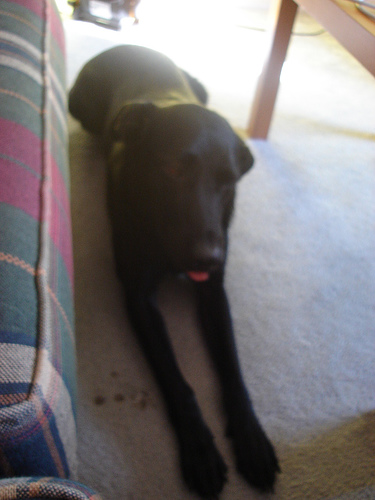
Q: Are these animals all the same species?
A: Yes, all the animals are dogs.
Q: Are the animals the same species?
A: Yes, all the animals are dogs.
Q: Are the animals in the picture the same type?
A: Yes, all the animals are dogs.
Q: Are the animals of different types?
A: No, all the animals are dogs.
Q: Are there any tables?
A: Yes, there is a table.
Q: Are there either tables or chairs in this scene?
A: Yes, there is a table.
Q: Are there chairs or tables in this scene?
A: Yes, there is a table.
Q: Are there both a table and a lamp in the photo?
A: No, there is a table but no lamps.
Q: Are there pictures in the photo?
A: No, there are no pictures.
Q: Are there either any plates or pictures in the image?
A: No, there are no pictures or plates.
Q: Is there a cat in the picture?
A: No, there are no cats.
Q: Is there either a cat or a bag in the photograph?
A: No, there are no cats or bags.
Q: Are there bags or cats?
A: No, there are no cats or bags.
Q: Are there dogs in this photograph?
A: Yes, there are dogs.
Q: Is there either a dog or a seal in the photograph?
A: Yes, there are dogs.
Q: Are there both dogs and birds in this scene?
A: No, there are dogs but no birds.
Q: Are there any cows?
A: No, there are no cows.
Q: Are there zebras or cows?
A: No, there are no cows or zebras.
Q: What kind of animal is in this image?
A: The animal is dogs.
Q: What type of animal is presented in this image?
A: The animal is dogs.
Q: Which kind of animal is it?
A: The animals are dogs.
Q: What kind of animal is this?
A: These are dogs.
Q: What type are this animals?
A: These are dogs.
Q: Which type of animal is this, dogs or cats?
A: These are dogs.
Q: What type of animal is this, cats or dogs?
A: These are dogs.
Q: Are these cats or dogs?
A: These are dogs.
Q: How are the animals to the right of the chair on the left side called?
A: The animals are dogs.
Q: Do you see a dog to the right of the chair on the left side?
A: Yes, there are dogs to the right of the chair.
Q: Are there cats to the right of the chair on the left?
A: No, there are dogs to the right of the chair.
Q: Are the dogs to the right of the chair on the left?
A: Yes, the dogs are to the right of the chair.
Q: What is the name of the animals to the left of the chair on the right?
A: The animals are dogs.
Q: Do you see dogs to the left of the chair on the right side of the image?
A: Yes, there are dogs to the left of the chair.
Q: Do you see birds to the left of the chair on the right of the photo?
A: No, there are dogs to the left of the chair.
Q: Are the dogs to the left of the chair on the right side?
A: Yes, the dogs are to the left of the chair.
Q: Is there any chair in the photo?
A: Yes, there is a chair.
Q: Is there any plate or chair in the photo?
A: Yes, there is a chair.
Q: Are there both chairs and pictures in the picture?
A: No, there is a chair but no pictures.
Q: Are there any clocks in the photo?
A: No, there are no clocks.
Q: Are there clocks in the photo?
A: No, there are no clocks.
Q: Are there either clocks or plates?
A: No, there are no clocks or plates.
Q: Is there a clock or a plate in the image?
A: No, there are no clocks or plates.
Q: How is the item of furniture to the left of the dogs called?
A: The piece of furniture is a chair.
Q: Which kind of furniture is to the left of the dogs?
A: The piece of furniture is a chair.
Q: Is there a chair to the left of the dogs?
A: Yes, there is a chair to the left of the dogs.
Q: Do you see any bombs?
A: No, there are no bombs.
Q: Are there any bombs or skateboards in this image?
A: No, there are no bombs or skateboards.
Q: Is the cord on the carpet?
A: Yes, the cord is on the carpet.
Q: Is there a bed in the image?
A: No, there are no beds.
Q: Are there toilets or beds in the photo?
A: No, there are no beds or toilets.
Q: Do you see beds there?
A: No, there are no beds.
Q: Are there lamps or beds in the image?
A: No, there are no beds or lamps.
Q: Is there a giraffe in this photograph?
A: No, there are no giraffes.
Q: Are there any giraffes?
A: No, there are no giraffes.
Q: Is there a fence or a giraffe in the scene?
A: No, there are no giraffes or fences.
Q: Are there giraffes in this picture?
A: No, there are no giraffes.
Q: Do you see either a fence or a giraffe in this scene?
A: No, there are no giraffes or fences.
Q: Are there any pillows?
A: No, there are no pillows.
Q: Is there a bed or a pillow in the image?
A: No, there are no pillows or beds.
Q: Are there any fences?
A: No, there are no fences.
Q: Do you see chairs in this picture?
A: Yes, there is a chair.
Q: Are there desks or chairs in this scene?
A: Yes, there is a chair.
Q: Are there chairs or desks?
A: Yes, there is a chair.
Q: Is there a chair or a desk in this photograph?
A: Yes, there is a chair.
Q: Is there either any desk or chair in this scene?
A: Yes, there is a chair.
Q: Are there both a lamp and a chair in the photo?
A: No, there is a chair but no lamps.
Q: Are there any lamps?
A: No, there are no lamps.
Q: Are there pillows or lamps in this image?
A: No, there are no lamps or pillows.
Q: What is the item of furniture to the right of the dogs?
A: The piece of furniture is a chair.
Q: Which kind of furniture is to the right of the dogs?
A: The piece of furniture is a chair.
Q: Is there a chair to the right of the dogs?
A: Yes, there is a chair to the right of the dogs.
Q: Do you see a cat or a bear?
A: No, there are no cats or bears.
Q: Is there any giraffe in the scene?
A: No, there are no giraffes.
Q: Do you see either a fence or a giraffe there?
A: No, there are no giraffes or fences.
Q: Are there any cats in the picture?
A: No, there are no cats.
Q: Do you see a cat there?
A: No, there are no cats.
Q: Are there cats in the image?
A: No, there are no cats.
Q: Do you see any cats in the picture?
A: No, there are no cats.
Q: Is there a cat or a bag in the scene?
A: No, there are no cats or bags.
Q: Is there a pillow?
A: No, there are no pillows.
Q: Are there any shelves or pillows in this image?
A: No, there are no pillows or shelves.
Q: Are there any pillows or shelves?
A: No, there are no pillows or shelves.